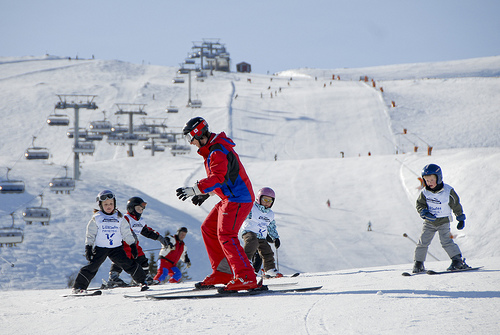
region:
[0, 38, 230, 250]
long ski lift with many chairs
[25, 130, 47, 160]
chair hanging from ski lift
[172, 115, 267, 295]
man skiing on snow covered slope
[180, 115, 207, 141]
helmet on man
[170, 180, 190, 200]
black and white glove on man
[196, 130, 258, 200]
red, blue and black coat on man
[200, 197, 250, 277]
red pants on man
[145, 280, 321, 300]
long black ski on man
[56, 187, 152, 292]
child skiing near man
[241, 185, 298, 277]
small child skiing behind man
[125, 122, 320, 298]
a skier instructor on a slope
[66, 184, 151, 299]
a small young skier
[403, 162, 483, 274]
a small young skier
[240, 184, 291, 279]
a small young skier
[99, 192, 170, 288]
a small young skier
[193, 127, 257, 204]
a red and blue winter jacket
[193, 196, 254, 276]
red and blue striped snow pants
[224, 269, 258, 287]
a red snow boot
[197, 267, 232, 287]
a red snow boot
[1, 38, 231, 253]
a mountain ski lift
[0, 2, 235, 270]
The ski lifts are empty.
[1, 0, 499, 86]
The sky is blue.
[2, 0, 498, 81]
The sky is cloudless.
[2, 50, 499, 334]
The ground is covered in snow.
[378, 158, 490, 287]
The child is wearing skis.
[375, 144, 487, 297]
The child is wearing a helmet.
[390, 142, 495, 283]
Child's helmet is blue.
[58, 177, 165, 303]
The girl is wearing skis.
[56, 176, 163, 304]
The girl is wearing sun goggles.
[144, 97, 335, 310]
The man is wearing skis.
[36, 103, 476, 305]
The kids are on skis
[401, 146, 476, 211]
The kid is wearing a blue helmet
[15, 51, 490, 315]
The mountain is covered in snow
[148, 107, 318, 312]
Person with a red and blue jacket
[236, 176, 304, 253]
Kid is wearing a pink helmet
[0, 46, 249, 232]
Silver lift chairs up the mountain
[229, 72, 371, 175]
People riding down the mountain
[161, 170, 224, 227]
The person is wearing black and white gloves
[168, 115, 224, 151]
Person is wearing white and red goggles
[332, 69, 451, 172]
Orange barrels down the mountain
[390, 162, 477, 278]
this is a child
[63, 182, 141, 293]
this is a child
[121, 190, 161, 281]
this is a child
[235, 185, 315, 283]
this is a child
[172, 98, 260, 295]
this is a person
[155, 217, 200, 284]
this is a person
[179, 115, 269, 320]
the person is ice skating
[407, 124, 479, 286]
the child is ice skating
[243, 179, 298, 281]
the child is ice skating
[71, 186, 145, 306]
the child is ice skating